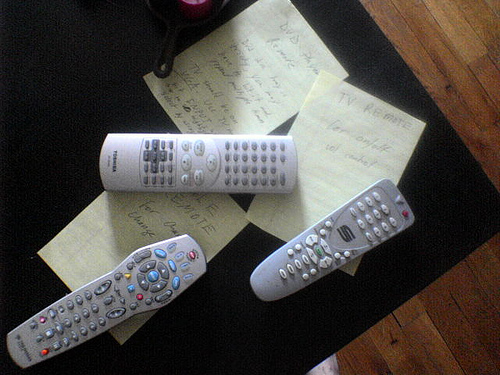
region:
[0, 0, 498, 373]
corner of black table above wood floor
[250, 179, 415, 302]
gray remote control with white buttons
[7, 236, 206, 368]
remote control with multi colored buttons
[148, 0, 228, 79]
handle of pan over paper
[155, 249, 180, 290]
three blue curved buttons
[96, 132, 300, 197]
silver television remote control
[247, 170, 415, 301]
silver remote control on black table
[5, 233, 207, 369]
silver remote control on television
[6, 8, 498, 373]
brown wooden floor under black table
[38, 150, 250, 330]
paper with writing on table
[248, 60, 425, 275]
paper identifying control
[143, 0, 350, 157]
paper with instructions for using electronics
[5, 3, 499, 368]
dark black mahogany table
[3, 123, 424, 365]
three remote devices sitting on a table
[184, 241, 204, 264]
red button on remote device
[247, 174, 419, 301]
this is a remote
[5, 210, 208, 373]
this is a remote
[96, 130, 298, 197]
this is a remote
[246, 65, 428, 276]
this is a piece of paper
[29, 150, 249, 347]
this is a piece of paper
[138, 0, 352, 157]
this is a piece of paper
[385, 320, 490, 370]
this is a brown surface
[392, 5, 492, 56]
this is a brown surface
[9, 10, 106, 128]
this is a black surface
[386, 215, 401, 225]
a key on a keyboard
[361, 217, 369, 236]
a key on a keyboard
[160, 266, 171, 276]
a key on a keyboard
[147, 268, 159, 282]
A button on a remote.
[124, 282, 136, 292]
A button on a remote.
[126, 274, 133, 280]
A button on a remote.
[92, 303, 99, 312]
A button on a remote.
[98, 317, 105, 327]
A button on a remote.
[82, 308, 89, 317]
A button on a remote.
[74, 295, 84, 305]
A button on a remote.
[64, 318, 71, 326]
A button on a remote.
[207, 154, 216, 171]
A button on a remote.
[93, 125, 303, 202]
A gray remote control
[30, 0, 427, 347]
Three pieces of white paper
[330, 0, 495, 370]
A brown wooden floor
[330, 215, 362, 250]
"S" written on remote control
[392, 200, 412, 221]
A tiny red button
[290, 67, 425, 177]
Writing on a white paper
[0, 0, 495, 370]
A black wooden table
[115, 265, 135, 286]
A tiny yellow button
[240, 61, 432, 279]
A rectangular piece of paper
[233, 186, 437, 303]
The grey remote has white buttons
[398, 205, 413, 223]
The button is red